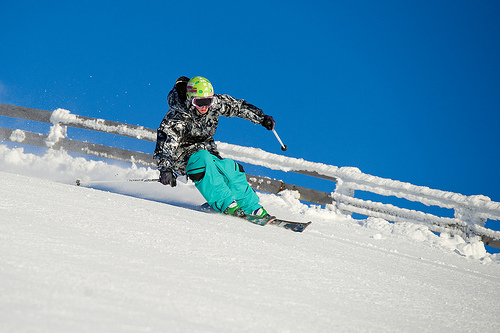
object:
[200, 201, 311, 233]
ski boots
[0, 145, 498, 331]
snow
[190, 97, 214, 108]
goggles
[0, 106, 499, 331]
white snow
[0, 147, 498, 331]
ground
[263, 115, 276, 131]
glove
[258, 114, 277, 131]
hand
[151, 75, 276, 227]
person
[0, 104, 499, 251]
fence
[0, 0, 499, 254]
sky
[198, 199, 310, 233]
speeding down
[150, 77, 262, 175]
jacket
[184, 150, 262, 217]
pants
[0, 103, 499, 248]
snow